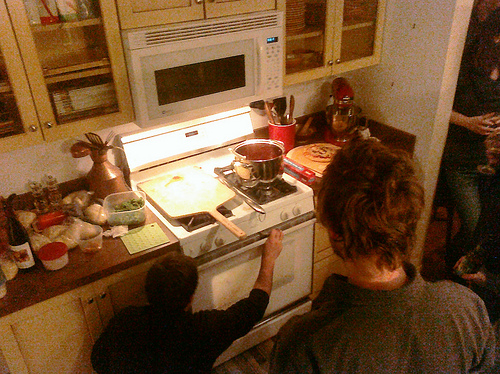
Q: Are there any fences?
A: No, there are no fences.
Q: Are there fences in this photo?
A: No, there are no fences.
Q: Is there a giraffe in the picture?
A: No, there are no giraffes.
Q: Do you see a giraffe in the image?
A: No, there are no giraffes.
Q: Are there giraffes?
A: No, there are no giraffes.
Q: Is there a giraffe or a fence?
A: No, there are no giraffes or fences.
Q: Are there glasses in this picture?
A: No, there are no glasses.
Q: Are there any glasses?
A: No, there are no glasses.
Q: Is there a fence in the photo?
A: No, there are no fences.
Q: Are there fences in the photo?
A: No, there are no fences.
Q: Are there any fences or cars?
A: No, there are no fences or cars.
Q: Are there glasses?
A: No, there are no glasses.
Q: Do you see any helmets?
A: No, there are no helmets.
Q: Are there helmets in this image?
A: No, there are no helmets.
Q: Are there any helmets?
A: No, there are no helmets.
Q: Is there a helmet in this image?
A: No, there are no helmets.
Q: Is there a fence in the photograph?
A: No, there are no fences.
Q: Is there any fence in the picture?
A: No, there are no fences.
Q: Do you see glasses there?
A: No, there are no glasses.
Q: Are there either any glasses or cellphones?
A: No, there are no glasses or cellphones.